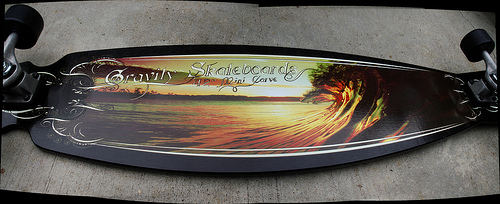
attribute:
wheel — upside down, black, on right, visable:
[459, 26, 495, 63]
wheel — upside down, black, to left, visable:
[4, 5, 45, 47]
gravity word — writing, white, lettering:
[105, 68, 181, 86]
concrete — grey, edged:
[2, 3, 499, 203]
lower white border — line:
[43, 116, 473, 162]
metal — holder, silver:
[2, 32, 41, 103]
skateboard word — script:
[185, 61, 302, 81]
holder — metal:
[468, 50, 499, 107]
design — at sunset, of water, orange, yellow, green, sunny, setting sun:
[65, 57, 437, 138]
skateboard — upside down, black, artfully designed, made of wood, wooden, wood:
[3, 4, 496, 176]